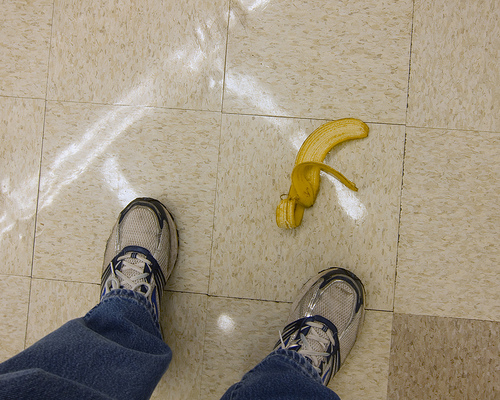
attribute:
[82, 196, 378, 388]
footwear — black, white, athletic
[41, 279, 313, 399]
jeans — blue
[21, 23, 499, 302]
floor tiles — tan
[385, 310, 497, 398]
tile — brown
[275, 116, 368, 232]
banana — yellow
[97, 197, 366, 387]
shoes — blue, white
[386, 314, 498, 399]
darktile — darker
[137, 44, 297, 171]
tiles — white light reflectedin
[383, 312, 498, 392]
tile — dark brown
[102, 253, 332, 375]
shoe laces — white 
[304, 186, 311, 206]
mark — brown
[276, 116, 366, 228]
peel — banana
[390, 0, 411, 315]
lines — grout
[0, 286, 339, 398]
jeans — blue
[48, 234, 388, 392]
pant — blue 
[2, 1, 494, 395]
tile flooring — grey, brown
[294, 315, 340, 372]
laces — white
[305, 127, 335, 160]
interior — white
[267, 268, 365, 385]
shoe — white, blue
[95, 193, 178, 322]
shoe — white, blue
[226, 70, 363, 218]
streak — sun 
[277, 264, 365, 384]
sneaker — white, blue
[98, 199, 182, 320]
sneaker — white, blue